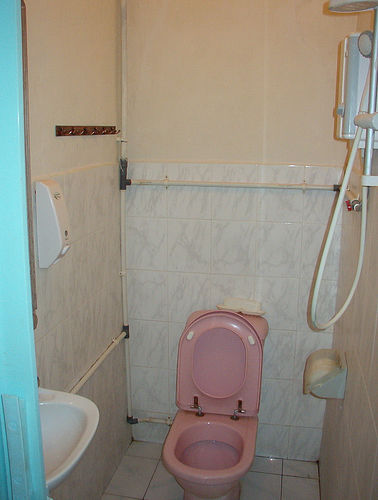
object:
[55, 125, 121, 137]
hanger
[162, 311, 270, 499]
comode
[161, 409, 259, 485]
seat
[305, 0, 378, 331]
shower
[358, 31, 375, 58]
head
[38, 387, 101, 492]
sink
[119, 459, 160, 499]
tile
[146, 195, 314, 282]
wall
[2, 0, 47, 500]
door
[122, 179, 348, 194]
pipes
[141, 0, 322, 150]
wall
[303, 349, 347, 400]
paper holder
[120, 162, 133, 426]
connectors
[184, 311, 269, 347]
water tank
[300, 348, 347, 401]
toiler paper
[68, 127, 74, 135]
hooks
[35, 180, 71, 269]
soap dispenser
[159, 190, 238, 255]
tiles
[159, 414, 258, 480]
bowl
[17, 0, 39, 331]
mirror